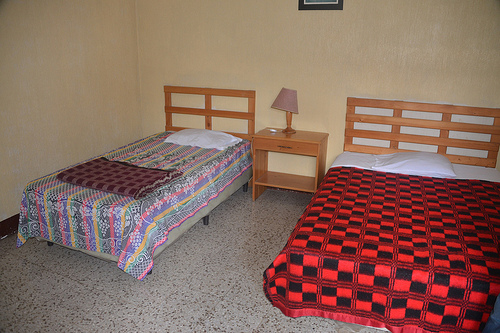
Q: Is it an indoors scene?
A: Yes, it is indoors.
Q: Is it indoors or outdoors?
A: It is indoors.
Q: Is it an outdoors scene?
A: No, it is indoors.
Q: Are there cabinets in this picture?
A: No, there are no cabinets.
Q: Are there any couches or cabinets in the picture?
A: No, there are no cabinets or couches.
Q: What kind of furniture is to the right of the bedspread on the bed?
A: The piece of furniture is an end table.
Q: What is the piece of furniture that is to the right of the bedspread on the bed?
A: The piece of furniture is an end table.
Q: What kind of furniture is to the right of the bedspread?
A: The piece of furniture is an end table.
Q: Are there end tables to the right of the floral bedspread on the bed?
A: Yes, there is an end table to the right of the bed spread.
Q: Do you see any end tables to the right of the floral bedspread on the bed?
A: Yes, there is an end table to the right of the bed spread.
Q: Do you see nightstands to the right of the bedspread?
A: No, there is an end table to the right of the bedspread.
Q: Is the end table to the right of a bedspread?
A: Yes, the end table is to the right of a bedspread.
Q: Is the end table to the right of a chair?
A: No, the end table is to the right of a bedspread.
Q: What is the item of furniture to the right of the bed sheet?
A: The piece of furniture is an end table.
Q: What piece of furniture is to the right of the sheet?
A: The piece of furniture is an end table.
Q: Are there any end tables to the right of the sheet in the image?
A: Yes, there is an end table to the right of the sheet.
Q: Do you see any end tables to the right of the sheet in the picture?
A: Yes, there is an end table to the right of the sheet.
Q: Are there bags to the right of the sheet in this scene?
A: No, there is an end table to the right of the sheet.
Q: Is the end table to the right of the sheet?
A: Yes, the end table is to the right of the sheet.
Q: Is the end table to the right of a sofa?
A: No, the end table is to the right of the sheet.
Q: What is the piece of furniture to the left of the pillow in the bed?
A: The piece of furniture is an end table.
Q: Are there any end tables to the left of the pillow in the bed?
A: Yes, there is an end table to the left of the pillow.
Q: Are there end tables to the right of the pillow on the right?
A: No, the end table is to the left of the pillow.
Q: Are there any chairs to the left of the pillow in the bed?
A: No, there is an end table to the left of the pillow.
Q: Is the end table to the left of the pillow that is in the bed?
A: Yes, the end table is to the left of the pillow.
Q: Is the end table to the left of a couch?
A: No, the end table is to the left of the pillow.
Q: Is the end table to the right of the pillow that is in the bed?
A: No, the end table is to the left of the pillow.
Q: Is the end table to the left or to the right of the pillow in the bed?
A: The end table is to the left of the pillow.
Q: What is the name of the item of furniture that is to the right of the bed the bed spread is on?
A: The piece of furniture is an end table.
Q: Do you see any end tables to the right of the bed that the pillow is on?
A: Yes, there is an end table to the right of the bed.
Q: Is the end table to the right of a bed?
A: Yes, the end table is to the right of a bed.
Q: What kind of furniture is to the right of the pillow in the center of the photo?
A: The piece of furniture is an end table.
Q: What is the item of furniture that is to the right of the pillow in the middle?
A: The piece of furniture is an end table.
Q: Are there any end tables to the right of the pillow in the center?
A: Yes, there is an end table to the right of the pillow.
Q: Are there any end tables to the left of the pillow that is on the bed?
A: No, the end table is to the right of the pillow.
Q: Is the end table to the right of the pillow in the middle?
A: Yes, the end table is to the right of the pillow.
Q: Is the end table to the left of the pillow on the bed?
A: No, the end table is to the right of the pillow.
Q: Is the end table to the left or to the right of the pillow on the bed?
A: The end table is to the right of the pillow.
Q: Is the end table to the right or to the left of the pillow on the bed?
A: The end table is to the right of the pillow.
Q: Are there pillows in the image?
A: Yes, there is a pillow.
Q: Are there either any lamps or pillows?
A: Yes, there is a pillow.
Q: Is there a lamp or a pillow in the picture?
A: Yes, there is a pillow.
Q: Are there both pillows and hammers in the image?
A: No, there is a pillow but no hammers.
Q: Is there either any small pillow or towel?
A: Yes, there is a small pillow.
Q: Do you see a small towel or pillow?
A: Yes, there is a small pillow.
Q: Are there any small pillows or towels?
A: Yes, there is a small pillow.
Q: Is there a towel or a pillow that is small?
A: Yes, the pillow is small.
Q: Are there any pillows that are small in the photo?
A: Yes, there is a small pillow.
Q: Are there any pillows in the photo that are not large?
A: Yes, there is a small pillow.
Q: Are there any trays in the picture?
A: No, there are no trays.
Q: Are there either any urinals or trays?
A: No, there are no trays or urinals.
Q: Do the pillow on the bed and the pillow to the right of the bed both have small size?
A: Yes, both the pillow and the pillow are small.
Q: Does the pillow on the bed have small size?
A: Yes, the pillow is small.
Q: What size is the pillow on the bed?
A: The pillow is small.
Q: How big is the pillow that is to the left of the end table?
A: The pillow is small.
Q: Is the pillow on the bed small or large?
A: The pillow is small.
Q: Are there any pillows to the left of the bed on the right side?
A: Yes, there is a pillow to the left of the bed.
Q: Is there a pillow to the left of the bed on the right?
A: Yes, there is a pillow to the left of the bed.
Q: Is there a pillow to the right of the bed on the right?
A: No, the pillow is to the left of the bed.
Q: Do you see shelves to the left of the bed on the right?
A: No, there is a pillow to the left of the bed.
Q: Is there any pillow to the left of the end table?
A: Yes, there is a pillow to the left of the end table.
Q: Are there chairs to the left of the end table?
A: No, there is a pillow to the left of the end table.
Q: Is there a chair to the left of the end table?
A: No, there is a pillow to the left of the end table.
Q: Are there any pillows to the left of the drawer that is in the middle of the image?
A: Yes, there is a pillow to the left of the drawer.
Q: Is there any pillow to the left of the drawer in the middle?
A: Yes, there is a pillow to the left of the drawer.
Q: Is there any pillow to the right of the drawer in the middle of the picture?
A: No, the pillow is to the left of the drawer.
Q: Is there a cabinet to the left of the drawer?
A: No, there is a pillow to the left of the drawer.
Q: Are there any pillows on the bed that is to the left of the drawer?
A: Yes, there is a pillow on the bed.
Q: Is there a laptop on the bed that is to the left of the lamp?
A: No, there is a pillow on the bed.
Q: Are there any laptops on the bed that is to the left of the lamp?
A: No, there is a pillow on the bed.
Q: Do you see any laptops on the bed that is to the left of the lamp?
A: No, there is a pillow on the bed.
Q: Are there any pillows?
A: Yes, there is a pillow.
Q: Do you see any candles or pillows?
A: Yes, there is a pillow.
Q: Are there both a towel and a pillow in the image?
A: No, there is a pillow but no towels.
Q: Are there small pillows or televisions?
A: Yes, there is a small pillow.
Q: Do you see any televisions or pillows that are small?
A: Yes, the pillow is small.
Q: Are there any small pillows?
A: Yes, there is a small pillow.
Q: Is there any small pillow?
A: Yes, there is a small pillow.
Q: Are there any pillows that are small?
A: Yes, there is a pillow that is small.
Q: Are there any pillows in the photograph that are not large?
A: Yes, there is a small pillow.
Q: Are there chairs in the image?
A: No, there are no chairs.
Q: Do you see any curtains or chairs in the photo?
A: No, there are no chairs or curtains.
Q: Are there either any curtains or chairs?
A: No, there are no chairs or curtains.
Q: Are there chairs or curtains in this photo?
A: No, there are no chairs or curtains.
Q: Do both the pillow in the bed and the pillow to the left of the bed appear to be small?
A: Yes, both the pillow and the pillow are small.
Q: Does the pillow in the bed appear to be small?
A: Yes, the pillow is small.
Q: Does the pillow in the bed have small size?
A: Yes, the pillow is small.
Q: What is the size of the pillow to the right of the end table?
A: The pillow is small.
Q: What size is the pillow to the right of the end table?
A: The pillow is small.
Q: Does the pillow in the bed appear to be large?
A: No, the pillow is small.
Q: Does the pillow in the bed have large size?
A: No, the pillow is small.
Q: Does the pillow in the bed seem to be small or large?
A: The pillow is small.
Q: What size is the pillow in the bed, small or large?
A: The pillow is small.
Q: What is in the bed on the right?
A: The pillow is in the bed.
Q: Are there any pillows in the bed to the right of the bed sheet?
A: Yes, there is a pillow in the bed.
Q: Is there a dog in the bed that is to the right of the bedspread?
A: No, there is a pillow in the bed.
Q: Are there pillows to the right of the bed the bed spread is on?
A: Yes, there is a pillow to the right of the bed.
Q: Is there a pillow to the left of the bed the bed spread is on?
A: No, the pillow is to the right of the bed.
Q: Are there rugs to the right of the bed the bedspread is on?
A: No, there is a pillow to the right of the bed.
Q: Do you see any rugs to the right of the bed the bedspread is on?
A: No, there is a pillow to the right of the bed.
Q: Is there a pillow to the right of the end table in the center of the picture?
A: Yes, there is a pillow to the right of the end table.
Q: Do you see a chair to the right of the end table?
A: No, there is a pillow to the right of the end table.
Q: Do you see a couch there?
A: No, there are no couches.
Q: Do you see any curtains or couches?
A: No, there are no couches or curtains.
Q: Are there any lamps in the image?
A: Yes, there is a lamp.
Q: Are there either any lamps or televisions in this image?
A: Yes, there is a lamp.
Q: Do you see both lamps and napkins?
A: No, there is a lamp but no napkins.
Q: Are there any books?
A: No, there are no books.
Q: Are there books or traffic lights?
A: No, there are no books or traffic lights.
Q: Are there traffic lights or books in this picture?
A: No, there are no books or traffic lights.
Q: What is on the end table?
A: The lamp is on the end table.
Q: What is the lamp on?
A: The lamp is on the end table.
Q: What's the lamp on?
A: The lamp is on the end table.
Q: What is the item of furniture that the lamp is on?
A: The piece of furniture is an end table.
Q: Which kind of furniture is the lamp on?
A: The lamp is on the end table.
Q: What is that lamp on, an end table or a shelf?
A: The lamp is on an end table.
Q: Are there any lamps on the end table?
A: Yes, there is a lamp on the end table.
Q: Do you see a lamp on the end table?
A: Yes, there is a lamp on the end table.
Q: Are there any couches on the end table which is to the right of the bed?
A: No, there is a lamp on the end table.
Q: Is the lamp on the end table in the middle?
A: Yes, the lamp is on the end table.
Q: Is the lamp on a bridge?
A: No, the lamp is on the end table.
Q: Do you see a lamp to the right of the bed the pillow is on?
A: Yes, there is a lamp to the right of the bed.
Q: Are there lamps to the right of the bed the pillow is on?
A: Yes, there is a lamp to the right of the bed.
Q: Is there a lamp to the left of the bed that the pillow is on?
A: No, the lamp is to the right of the bed.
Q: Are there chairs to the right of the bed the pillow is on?
A: No, there is a lamp to the right of the bed.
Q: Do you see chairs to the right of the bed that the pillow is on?
A: No, there is a lamp to the right of the bed.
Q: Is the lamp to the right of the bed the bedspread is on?
A: Yes, the lamp is to the right of the bed.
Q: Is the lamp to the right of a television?
A: No, the lamp is to the right of the bed.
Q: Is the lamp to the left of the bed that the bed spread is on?
A: No, the lamp is to the right of the bed.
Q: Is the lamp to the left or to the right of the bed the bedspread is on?
A: The lamp is to the right of the bed.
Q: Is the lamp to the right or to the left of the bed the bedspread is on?
A: The lamp is to the right of the bed.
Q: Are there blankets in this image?
A: Yes, there is a blanket.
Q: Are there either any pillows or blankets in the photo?
A: Yes, there is a blanket.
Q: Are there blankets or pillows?
A: Yes, there is a blanket.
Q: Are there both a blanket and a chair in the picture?
A: No, there is a blanket but no chairs.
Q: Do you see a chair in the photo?
A: No, there are no chairs.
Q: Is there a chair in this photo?
A: No, there are no chairs.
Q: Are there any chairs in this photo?
A: No, there are no chairs.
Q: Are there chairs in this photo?
A: No, there are no chairs.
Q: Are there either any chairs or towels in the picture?
A: No, there are no chairs or towels.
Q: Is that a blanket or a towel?
A: That is a blanket.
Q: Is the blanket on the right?
A: Yes, the blanket is on the right of the image.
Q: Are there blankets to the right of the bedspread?
A: Yes, there is a blanket to the right of the bedspread.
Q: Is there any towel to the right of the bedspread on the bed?
A: No, there is a blanket to the right of the bedspread.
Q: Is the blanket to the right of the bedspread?
A: Yes, the blanket is to the right of the bedspread.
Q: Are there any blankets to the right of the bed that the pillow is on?
A: Yes, there is a blanket to the right of the bed.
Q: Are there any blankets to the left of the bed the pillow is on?
A: No, the blanket is to the right of the bed.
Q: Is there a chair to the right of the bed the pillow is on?
A: No, there is a blanket to the right of the bed.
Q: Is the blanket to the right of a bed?
A: Yes, the blanket is to the right of a bed.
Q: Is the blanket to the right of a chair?
A: No, the blanket is to the right of a bed.